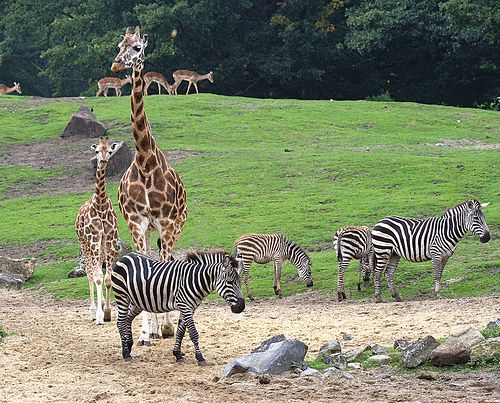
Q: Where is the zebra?
A: In dirt.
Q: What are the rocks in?
A: Dirt.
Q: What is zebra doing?
A: Standing.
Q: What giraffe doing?
A: Standing.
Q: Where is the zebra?
A: On field.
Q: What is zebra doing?
A: Walking.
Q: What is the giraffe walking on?
A: Dirt.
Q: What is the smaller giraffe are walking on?
A: Dirt.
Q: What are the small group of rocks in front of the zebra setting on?
A: The ground.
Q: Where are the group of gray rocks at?
A: In front of the zebra.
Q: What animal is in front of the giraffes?
A: Zebras.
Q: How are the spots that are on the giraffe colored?
A: Brown and tan.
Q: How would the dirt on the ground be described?
A: As tan.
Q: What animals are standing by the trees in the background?
A: Impala.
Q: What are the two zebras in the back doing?
A: Grazing.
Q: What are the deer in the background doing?
A: Grazing.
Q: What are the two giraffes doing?
A: Walking together.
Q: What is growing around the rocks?
A: Grass.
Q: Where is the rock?
A: In bald spot on the grass.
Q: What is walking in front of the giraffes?
A: Zebras.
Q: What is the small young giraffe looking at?
A: The camera.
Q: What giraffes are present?
A: An adult and a baby.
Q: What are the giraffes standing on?
A: An area of tan dirt.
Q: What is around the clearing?
A: A line of trees.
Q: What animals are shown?
A: Deer, zebras, and giraffes.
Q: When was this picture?
A: Daytime.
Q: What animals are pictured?
A: Zebras and giraffes.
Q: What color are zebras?
A: Black and white.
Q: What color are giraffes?
A: Brown and white.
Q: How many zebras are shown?
A: Four.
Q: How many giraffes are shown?
A: Two.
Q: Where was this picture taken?
A: A field.